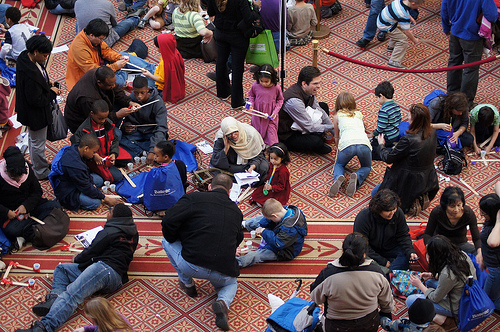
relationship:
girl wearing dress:
[243, 64, 283, 147] [250, 83, 282, 140]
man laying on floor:
[37, 206, 137, 327] [36, 44, 396, 323]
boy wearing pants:
[373, 1, 422, 68] [373, 29, 411, 69]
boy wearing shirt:
[373, 1, 422, 68] [374, 0, 411, 31]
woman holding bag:
[204, 2, 256, 107] [241, 24, 273, 70]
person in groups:
[353, 189, 418, 269] [55, 46, 297, 328]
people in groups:
[29, 22, 484, 308] [68, 57, 499, 324]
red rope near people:
[320, 44, 496, 74] [29, 22, 484, 308]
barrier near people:
[296, 37, 332, 103] [29, 22, 484, 308]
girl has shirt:
[326, 78, 378, 191] [323, 94, 419, 164]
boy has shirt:
[355, 82, 437, 192] [370, 100, 417, 153]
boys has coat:
[143, 23, 196, 105] [180, 102, 298, 161]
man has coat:
[153, 151, 283, 314] [162, 174, 248, 295]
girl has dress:
[229, 57, 288, 139] [243, 83, 283, 145]